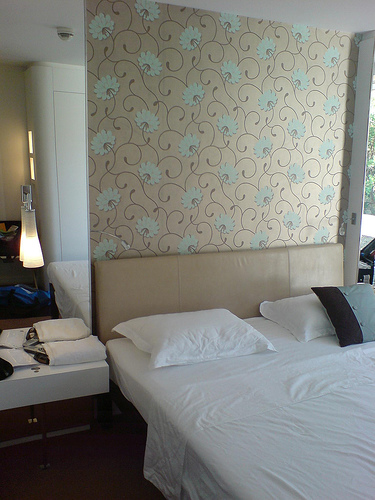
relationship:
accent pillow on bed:
[313, 285, 373, 351] [105, 318, 374, 499]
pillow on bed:
[111, 308, 278, 371] [101, 282, 374, 496]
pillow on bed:
[111, 308, 278, 371] [101, 310, 371, 475]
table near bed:
[0, 366, 128, 409] [88, 261, 372, 464]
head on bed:
[115, 236, 352, 343] [89, 242, 372, 499]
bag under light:
[1, 279, 59, 320] [12, 179, 51, 295]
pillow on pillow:
[125, 309, 280, 371] [258, 294, 328, 344]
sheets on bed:
[196, 367, 337, 426] [89, 242, 372, 499]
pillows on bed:
[117, 303, 339, 361] [89, 242, 372, 499]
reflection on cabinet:
[24, 64, 93, 263] [26, 61, 91, 268]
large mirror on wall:
[0, 0, 92, 348] [122, 60, 263, 203]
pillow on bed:
[111, 308, 278, 371] [106, 254, 351, 472]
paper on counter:
[1, 324, 38, 351] [5, 324, 97, 390]